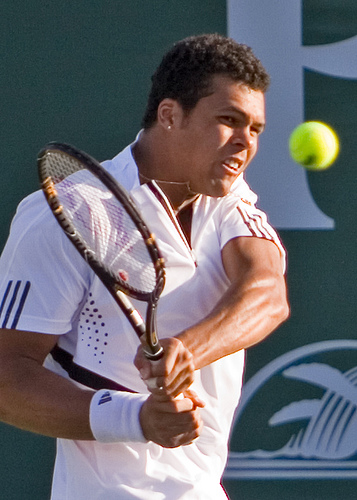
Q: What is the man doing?
A: Playing tennis.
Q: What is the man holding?
A: A racket.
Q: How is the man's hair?
A: Curly.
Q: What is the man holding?
A: Racket.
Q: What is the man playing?
A: Tennis.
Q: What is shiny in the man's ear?
A: Earring.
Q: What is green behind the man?
A: Wall.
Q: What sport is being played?
A: Tennis.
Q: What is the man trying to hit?
A: Tennis ball.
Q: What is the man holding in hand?
A: Racket.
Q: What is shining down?
A: Sun.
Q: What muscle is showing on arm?
A: Forearm.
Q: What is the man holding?
A: A racquet.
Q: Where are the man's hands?
A: On the handle.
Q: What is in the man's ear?
A: An earring.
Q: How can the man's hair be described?
A: Curly.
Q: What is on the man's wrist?
A: Wristband.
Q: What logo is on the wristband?
A: Adidas.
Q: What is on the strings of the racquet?
A: A dampener.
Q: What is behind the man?
A: A green wall.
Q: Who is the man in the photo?
A: Tennis player.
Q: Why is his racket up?
A: Hit the ball.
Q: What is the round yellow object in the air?
A: Tennis ball.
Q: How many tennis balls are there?
A: One.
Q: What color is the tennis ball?
A: Yellow.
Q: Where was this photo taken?
A: Tennis court.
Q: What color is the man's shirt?
A: White.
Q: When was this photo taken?
A: Daytime.